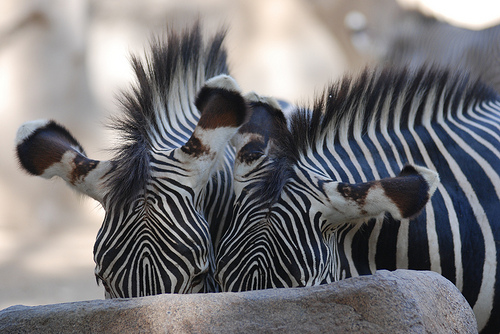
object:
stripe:
[166, 183, 190, 250]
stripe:
[396, 104, 459, 298]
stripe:
[413, 92, 485, 306]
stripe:
[431, 86, 499, 230]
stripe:
[328, 120, 361, 186]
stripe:
[318, 126, 350, 185]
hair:
[92, 8, 214, 185]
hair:
[252, 29, 497, 161]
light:
[138, 291, 243, 333]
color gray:
[51, 285, 454, 331]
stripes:
[107, 207, 153, 263]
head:
[12, 68, 254, 294]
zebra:
[212, 52, 499, 332]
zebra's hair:
[106, 124, 178, 213]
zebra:
[8, 20, 247, 297]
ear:
[324, 157, 421, 237]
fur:
[127, 21, 225, 167]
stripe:
[432, 89, 482, 317]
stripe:
[421, 85, 498, 296]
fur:
[416, 111, 493, 274]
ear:
[231, 86, 291, 189]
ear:
[177, 74, 242, 170]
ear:
[15, 113, 115, 198]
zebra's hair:
[298, 62, 496, 147]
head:
[204, 122, 442, 307]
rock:
[4, 271, 484, 329]